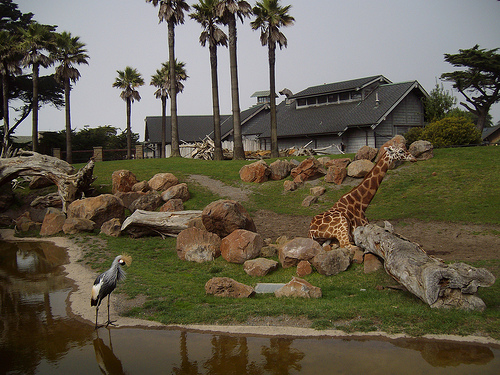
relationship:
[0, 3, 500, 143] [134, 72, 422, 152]
sky above building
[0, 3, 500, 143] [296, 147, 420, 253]
sky above giraffe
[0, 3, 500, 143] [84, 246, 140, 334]
sky above bird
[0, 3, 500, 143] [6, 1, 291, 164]
sky above trees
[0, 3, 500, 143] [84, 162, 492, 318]
sky above grass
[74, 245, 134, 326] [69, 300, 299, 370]
bird wading on water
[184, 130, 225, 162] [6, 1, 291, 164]
pile next trees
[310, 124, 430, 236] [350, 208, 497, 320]
giraffe next log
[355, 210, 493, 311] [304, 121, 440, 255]
log next giraffe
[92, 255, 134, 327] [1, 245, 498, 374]
bird next water